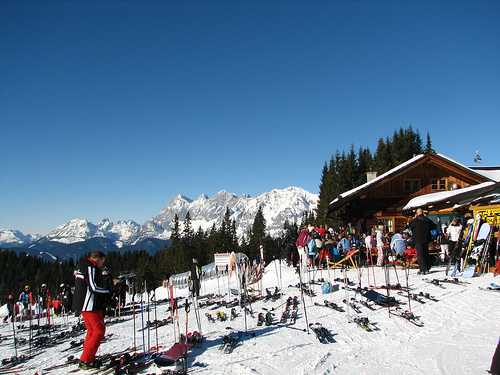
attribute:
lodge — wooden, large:
[323, 151, 497, 267]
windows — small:
[399, 176, 452, 194]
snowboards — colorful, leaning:
[453, 212, 499, 288]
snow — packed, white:
[34, 281, 482, 371]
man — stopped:
[65, 247, 120, 373]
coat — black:
[57, 258, 119, 313]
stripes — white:
[81, 264, 98, 314]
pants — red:
[70, 308, 111, 374]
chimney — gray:
[365, 164, 376, 182]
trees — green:
[314, 120, 445, 190]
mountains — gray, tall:
[41, 185, 331, 233]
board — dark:
[144, 332, 212, 373]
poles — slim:
[124, 276, 211, 372]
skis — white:
[397, 304, 429, 331]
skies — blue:
[4, 1, 500, 139]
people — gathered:
[20, 201, 468, 371]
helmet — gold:
[21, 282, 30, 294]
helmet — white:
[56, 279, 70, 291]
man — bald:
[412, 205, 443, 282]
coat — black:
[403, 214, 441, 247]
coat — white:
[444, 222, 471, 243]